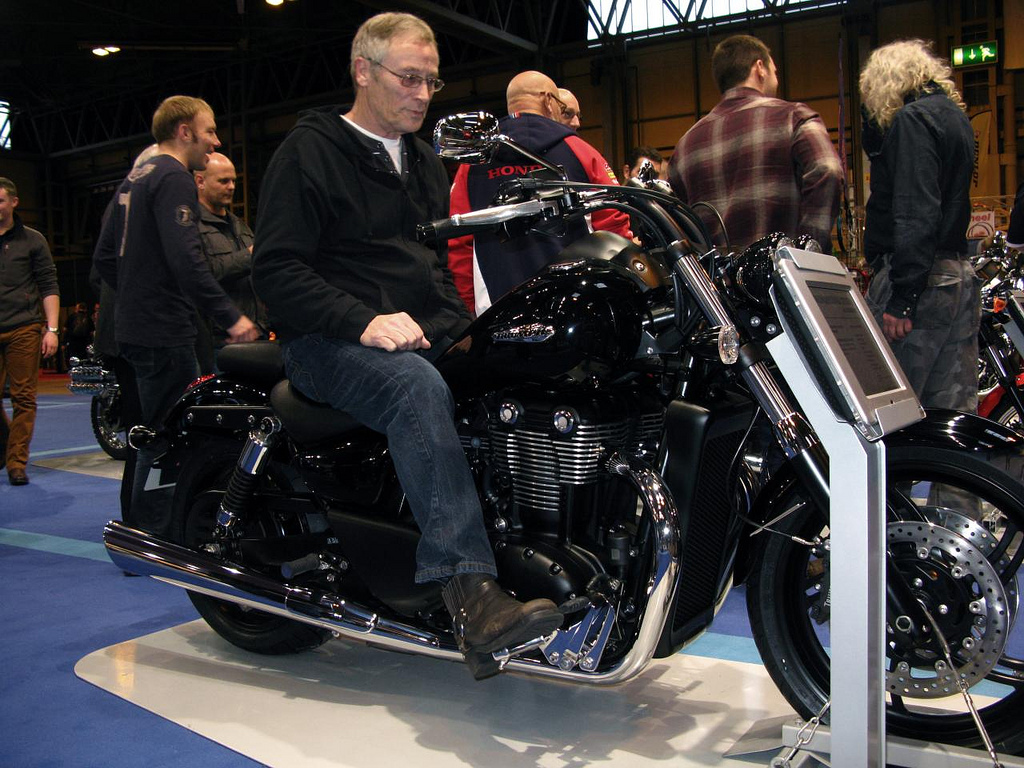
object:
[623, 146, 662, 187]
person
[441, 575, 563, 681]
boots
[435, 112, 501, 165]
rear mirror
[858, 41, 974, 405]
man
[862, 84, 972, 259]
black shirt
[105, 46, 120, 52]
light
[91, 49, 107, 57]
beam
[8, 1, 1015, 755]
room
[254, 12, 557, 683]
man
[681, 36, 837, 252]
man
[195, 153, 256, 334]
man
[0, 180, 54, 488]
man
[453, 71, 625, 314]
man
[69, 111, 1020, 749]
bike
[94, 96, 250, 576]
person